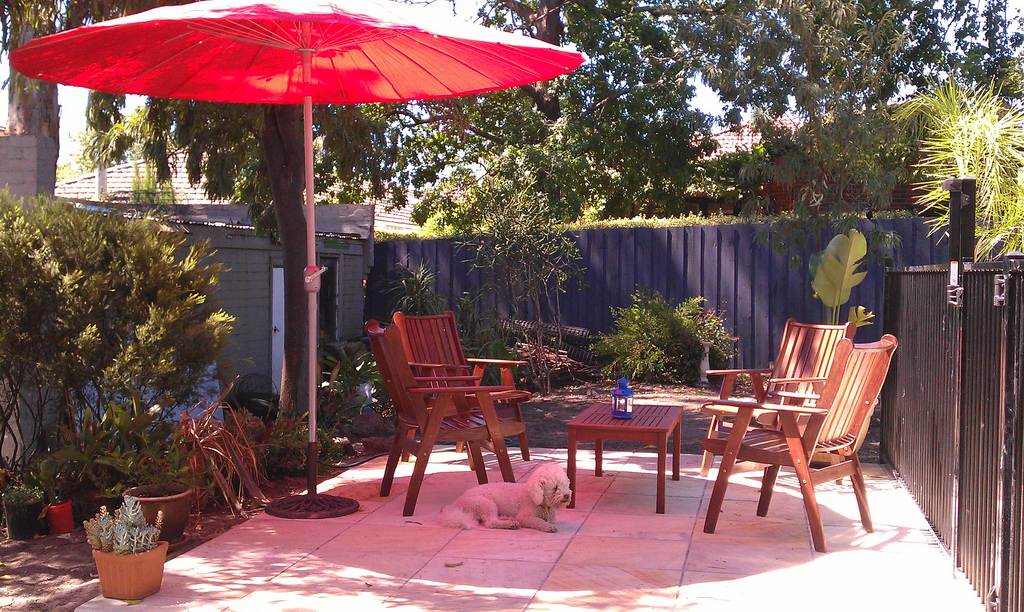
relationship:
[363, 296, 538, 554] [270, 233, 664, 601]
chair outside on porch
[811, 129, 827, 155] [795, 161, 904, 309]
leaf on stem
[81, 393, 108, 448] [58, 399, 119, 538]
leaf on stem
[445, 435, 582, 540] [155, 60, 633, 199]
dog sitting below umbrella